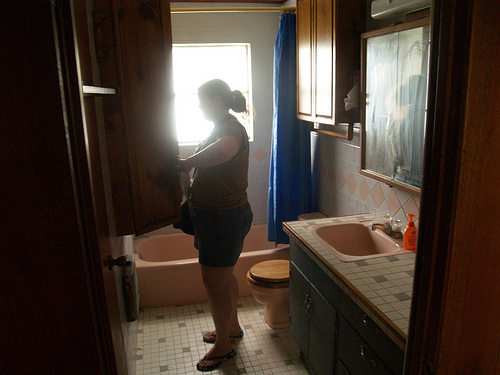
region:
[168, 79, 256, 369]
Woman using the towl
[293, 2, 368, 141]
Wooden cabinet in the bathroom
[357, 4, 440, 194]
Wooden picture frame with a picture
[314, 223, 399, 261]
Sink in the bathroom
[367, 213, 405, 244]
Faucet on top of the sink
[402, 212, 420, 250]
Small container of hand soap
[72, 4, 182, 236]
Towel that the woman is wiping her hands on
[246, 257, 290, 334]
Toilet on the ground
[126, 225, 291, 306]
Bathtub in the bathroom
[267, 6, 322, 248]
Blue shower curtains in the bathroom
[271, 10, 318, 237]
The curtain is blue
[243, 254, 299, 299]
The toilet seat cover is brown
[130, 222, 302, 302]
The bath tub is pink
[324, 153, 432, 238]
Pink diamond tile on the wall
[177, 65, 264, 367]
The woman is standing in the bathroom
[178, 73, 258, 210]
Woman wearing a brown shirt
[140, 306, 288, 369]
The flooring is grey and white tile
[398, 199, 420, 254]
Orange bottle on the counter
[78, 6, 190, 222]
The cabinet is open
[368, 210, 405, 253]
The faucet is silver with clear handles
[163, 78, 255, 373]
a woman standing in a bathroom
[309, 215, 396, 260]
a bathroom sink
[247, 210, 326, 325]
a toilet in the bathroom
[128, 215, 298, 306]
a bathtub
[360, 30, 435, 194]
the mirror above the sink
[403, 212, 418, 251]
the bottle for the hand soap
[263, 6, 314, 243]
the hanging shower curtain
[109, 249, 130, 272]
the door knob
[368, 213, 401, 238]
the water faucet fixture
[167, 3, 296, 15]
the shower curtain rod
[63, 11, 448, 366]
a woman standing in a bathroom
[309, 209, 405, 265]
a pink bathroom sink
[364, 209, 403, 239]
a bathroom sink faucet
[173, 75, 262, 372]
a woman wearing flip flops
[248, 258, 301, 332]
a pink toilet with a wooden seat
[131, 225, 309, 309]
a pink bath tub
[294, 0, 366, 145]
wooden bathroom cabinets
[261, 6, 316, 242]
a blue bathroom shower curtain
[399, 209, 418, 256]
a bottle of hand soap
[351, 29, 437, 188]
a bathroom mirror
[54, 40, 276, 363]
A woman opening a bathroom cabinet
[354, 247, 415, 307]
A few grey tiles on the counter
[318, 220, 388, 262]
A white sink on the counter top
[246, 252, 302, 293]
A smooth wooden toilet seat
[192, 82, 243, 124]
The woman has short hair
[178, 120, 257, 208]
The woman has a green shirt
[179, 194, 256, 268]
The woman is wearing blue shorts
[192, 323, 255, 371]
Flip flops on the woman's feet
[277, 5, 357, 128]
A wooden cabinet with two doors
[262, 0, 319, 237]
A blue shower curtain